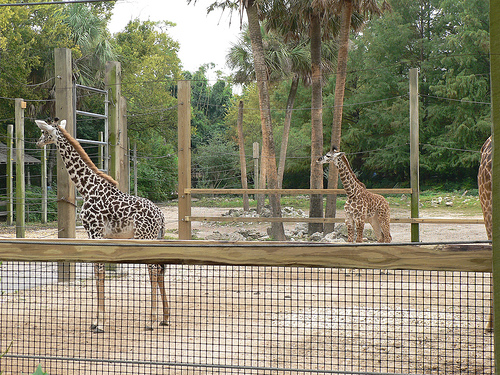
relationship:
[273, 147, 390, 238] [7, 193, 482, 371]
giraffe standing in field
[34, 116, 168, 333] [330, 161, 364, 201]
giraffe has neck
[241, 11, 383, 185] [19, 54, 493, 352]
trees along exhibit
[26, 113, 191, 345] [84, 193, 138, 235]
giraffe has spots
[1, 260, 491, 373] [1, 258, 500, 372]
fence made of fence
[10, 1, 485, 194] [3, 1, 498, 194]
leaves on trees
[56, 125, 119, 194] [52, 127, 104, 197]
fur on neck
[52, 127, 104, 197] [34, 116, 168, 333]
neck on giraffe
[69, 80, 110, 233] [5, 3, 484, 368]
door to exhibit